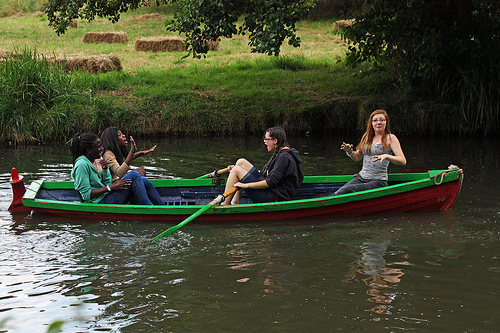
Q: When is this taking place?
A: Daytime.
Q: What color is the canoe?
A: Green and red.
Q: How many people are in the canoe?
A: Four.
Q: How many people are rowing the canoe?
A: One.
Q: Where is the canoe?
A: Water.